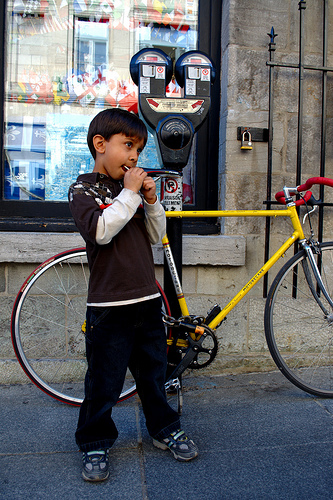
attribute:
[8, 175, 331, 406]
bike — racing bike, yellow framed, yellow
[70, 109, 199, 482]
boy — eating, biting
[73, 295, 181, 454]
pants — black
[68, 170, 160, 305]
shirt — brown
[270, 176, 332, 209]
handles — red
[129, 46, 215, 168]
parking meter — dual sided, black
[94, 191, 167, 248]
sleeves — white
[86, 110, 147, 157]
hair — brown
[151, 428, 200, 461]
shoe — gray, blue, grey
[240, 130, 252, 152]
padlock — locked, dark, yellow, silver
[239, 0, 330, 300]
gate — black iron, wrought iron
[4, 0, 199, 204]
window — dark framed, reflective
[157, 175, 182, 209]
no parking sticker — here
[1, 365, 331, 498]
sidewalk — paved